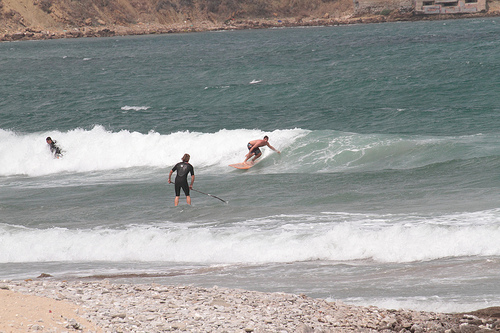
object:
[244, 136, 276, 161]
man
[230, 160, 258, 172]
board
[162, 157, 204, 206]
woman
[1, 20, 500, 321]
water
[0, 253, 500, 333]
beach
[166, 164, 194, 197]
wetsuit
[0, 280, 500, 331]
rock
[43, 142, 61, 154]
shirt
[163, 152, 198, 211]
man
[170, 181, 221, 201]
paddle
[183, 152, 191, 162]
hair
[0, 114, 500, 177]
waves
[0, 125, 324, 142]
tops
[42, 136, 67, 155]
person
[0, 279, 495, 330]
shore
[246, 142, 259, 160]
shorts